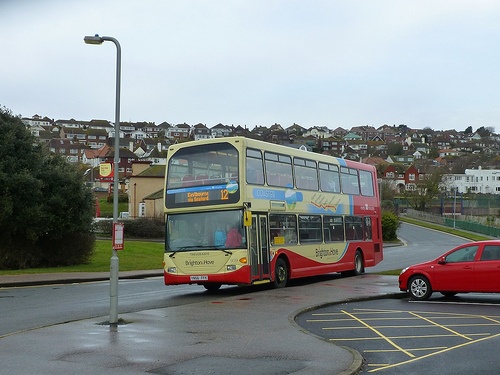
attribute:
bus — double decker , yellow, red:
[159, 129, 393, 294]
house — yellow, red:
[82, 138, 111, 163]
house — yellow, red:
[157, 124, 195, 144]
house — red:
[306, 124, 326, 144]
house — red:
[301, 122, 339, 140]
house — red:
[24, 109, 58, 132]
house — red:
[66, 124, 86, 138]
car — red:
[392, 238, 499, 305]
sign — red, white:
[112, 222, 128, 251]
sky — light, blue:
[2, 1, 499, 128]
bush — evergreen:
[2, 106, 94, 270]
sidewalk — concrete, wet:
[0, 271, 403, 373]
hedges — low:
[106, 208, 166, 238]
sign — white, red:
[111, 218, 124, 251]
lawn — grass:
[5, 233, 165, 275]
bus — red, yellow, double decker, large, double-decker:
[163, 136, 383, 292]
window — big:
[168, 143, 239, 189]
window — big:
[168, 208, 247, 252]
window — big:
[243, 145, 265, 186]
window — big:
[261, 147, 296, 191]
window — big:
[294, 154, 321, 192]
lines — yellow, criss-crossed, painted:
[306, 306, 499, 374]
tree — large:
[1, 105, 98, 268]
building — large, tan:
[127, 156, 164, 218]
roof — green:
[130, 156, 163, 178]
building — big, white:
[439, 166, 499, 196]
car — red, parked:
[398, 238, 498, 299]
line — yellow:
[340, 306, 411, 356]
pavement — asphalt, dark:
[298, 290, 499, 373]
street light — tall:
[83, 30, 124, 324]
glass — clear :
[168, 142, 239, 190]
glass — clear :
[247, 146, 264, 157]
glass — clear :
[246, 155, 265, 186]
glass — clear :
[318, 170, 340, 192]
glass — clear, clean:
[291, 161, 318, 192]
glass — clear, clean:
[164, 139, 236, 189]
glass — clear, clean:
[443, 240, 480, 262]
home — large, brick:
[382, 158, 419, 195]